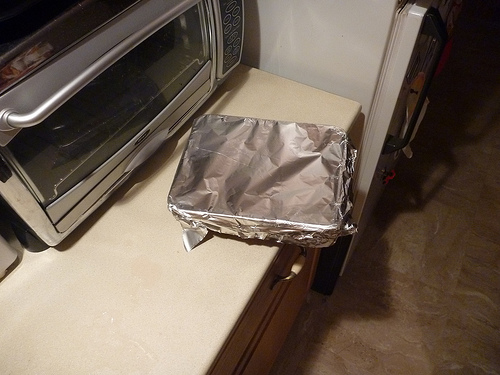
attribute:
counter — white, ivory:
[4, 65, 363, 373]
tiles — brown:
[369, 215, 497, 373]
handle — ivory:
[292, 262, 300, 275]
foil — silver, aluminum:
[168, 110, 359, 253]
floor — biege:
[388, 180, 488, 372]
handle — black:
[385, 11, 450, 154]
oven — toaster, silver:
[1, 0, 245, 244]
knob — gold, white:
[276, 250, 313, 285]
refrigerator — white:
[243, 0, 442, 291]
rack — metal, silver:
[12, 48, 204, 203]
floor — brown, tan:
[267, 2, 483, 371]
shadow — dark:
[270, 240, 393, 373]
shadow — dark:
[372, 3, 484, 213]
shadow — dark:
[417, 148, 483, 371]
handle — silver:
[2, 1, 200, 132]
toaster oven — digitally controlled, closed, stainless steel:
[2, 1, 248, 251]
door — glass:
[2, 2, 218, 250]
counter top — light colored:
[1, 61, 363, 372]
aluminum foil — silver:
[164, 111, 360, 254]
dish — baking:
[167, 101, 355, 243]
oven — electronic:
[12, 7, 246, 256]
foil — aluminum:
[167, 110, 352, 230]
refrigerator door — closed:
[328, 6, 450, 286]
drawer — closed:
[218, 132, 358, 368]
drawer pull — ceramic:
[271, 240, 314, 294]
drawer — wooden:
[210, 248, 309, 360]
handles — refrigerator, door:
[389, 14, 450, 156]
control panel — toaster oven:
[216, 2, 245, 75]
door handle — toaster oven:
[8, 6, 179, 132]